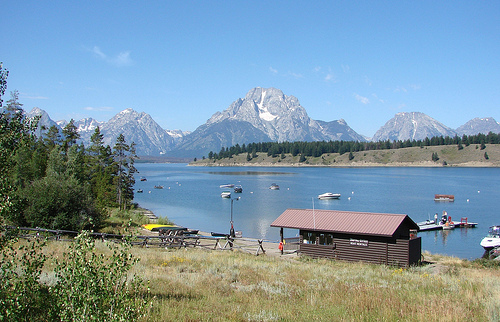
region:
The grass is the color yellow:
[168, 270, 285, 320]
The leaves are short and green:
[6, 270, 128, 315]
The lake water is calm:
[322, 165, 472, 192]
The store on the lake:
[271, 200, 430, 270]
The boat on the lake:
[311, 180, 346, 202]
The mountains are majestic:
[91, 82, 337, 156]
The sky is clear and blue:
[71, 17, 406, 74]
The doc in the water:
[415, 198, 480, 233]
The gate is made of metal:
[23, 219, 268, 254]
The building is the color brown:
[276, 203, 427, 270]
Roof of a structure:
[325, 214, 377, 229]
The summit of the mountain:
[256, 89, 268, 100]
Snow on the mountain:
[264, 113, 270, 119]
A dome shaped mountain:
[404, 113, 417, 117]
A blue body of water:
[372, 181, 421, 192]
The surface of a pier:
[427, 225, 439, 227]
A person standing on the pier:
[433, 213, 438, 223]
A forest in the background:
[295, 142, 322, 148]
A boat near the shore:
[480, 240, 490, 245]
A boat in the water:
[316, 192, 338, 199]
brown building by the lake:
[267, 200, 428, 269]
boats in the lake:
[143, 160, 499, 245]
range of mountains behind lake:
[33, 82, 494, 156]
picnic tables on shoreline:
[125, 218, 230, 246]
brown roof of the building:
[272, 205, 413, 234]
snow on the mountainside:
[255, 90, 276, 124]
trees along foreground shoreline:
[5, 101, 141, 319]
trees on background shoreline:
[212, 137, 493, 161]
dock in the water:
[421, 213, 473, 236]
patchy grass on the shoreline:
[17, 230, 480, 321]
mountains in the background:
[99, 61, 350, 165]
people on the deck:
[409, 190, 476, 269]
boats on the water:
[197, 167, 365, 209]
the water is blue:
[275, 144, 430, 240]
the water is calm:
[295, 155, 432, 214]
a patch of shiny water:
[204, 163, 290, 182]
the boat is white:
[302, 177, 344, 206]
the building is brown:
[268, 197, 418, 273]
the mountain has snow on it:
[192, 72, 329, 146]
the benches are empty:
[35, 212, 185, 248]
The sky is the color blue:
[148, 23, 442, 77]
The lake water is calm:
[344, 163, 430, 200]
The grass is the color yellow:
[193, 269, 425, 320]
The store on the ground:
[268, 193, 430, 275]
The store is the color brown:
[271, 199, 423, 267]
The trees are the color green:
[8, 127, 108, 209]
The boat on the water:
[311, 187, 350, 203]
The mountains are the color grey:
[88, 87, 388, 147]